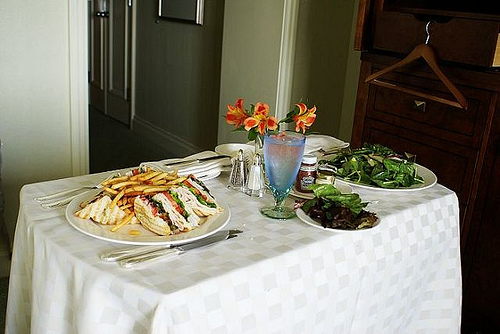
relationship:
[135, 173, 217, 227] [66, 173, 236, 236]
sandwich on plate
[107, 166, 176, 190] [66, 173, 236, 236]
fries on plate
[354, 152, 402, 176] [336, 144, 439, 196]
salad on plate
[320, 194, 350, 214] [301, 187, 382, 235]
salad on plate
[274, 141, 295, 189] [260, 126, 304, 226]
water in glass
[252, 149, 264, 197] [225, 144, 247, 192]
salt and pepper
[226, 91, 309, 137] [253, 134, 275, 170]
flowers in vase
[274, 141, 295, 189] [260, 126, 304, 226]
beverage in glass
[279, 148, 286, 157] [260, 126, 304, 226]
light blue glass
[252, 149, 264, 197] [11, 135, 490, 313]
salt on table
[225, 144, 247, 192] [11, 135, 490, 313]
pepper on table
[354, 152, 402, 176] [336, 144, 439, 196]
greens on plate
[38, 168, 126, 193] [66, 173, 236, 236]
utensils by plate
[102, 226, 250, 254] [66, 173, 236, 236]
utensils by plate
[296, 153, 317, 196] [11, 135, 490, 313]
bottle on table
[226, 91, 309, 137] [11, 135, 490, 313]
flowers on table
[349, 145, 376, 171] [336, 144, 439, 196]
greens on plate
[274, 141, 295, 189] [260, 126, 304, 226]
water for glass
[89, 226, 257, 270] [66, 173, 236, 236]
knives by plate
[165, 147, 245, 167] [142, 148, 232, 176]
knife on napkin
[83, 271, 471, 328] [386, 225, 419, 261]
tablecloth has pattern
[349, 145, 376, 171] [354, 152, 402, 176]
greens for salad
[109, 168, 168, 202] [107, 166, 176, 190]
gourmet french fries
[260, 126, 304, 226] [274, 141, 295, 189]
glass of water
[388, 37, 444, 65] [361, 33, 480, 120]
wooden coat hanger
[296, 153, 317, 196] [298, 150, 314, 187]
condiment in jar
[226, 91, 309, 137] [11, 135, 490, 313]
flowers on cart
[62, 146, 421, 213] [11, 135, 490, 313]
food on tray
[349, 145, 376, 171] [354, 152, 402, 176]
greens in salad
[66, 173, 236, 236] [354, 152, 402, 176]
plate of salad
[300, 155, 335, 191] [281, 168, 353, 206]
condiments on tray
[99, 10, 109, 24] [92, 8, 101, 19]
silver door knob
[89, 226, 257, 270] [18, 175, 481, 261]
knives on tray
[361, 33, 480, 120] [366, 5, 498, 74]
hanger on drawer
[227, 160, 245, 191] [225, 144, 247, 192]
shaker with pepper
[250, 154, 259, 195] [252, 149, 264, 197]
shaker with salt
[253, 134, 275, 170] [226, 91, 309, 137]
vase has lillies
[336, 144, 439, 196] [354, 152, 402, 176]
plate of salad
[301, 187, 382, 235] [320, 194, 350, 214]
plate has salad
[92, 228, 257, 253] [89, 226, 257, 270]
pair of knives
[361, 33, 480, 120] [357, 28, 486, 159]
hanger on chair